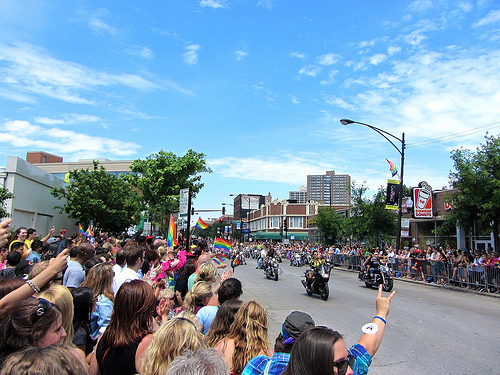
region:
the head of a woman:
[13, 287, 95, 362]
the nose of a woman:
[46, 313, 96, 350]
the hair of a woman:
[102, 280, 169, 340]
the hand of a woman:
[356, 282, 422, 320]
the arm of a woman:
[338, 278, 413, 362]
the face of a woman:
[29, 308, 81, 363]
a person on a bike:
[279, 248, 354, 308]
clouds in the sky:
[179, 9, 454, 107]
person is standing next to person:
[87, 279, 157, 372]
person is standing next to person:
[79, 261, 116, 361]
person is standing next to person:
[283, 327, 353, 372]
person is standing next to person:
[243, 284, 397, 372]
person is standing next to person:
[212, 300, 273, 371]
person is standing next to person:
[205, 300, 240, 344]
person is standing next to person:
[162, 347, 229, 372]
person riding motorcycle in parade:
[301, 249, 337, 300]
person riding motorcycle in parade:
[356, 257, 396, 294]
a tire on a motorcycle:
[318, 277, 332, 305]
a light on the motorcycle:
[317, 265, 330, 281]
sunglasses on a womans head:
[30, 295, 53, 322]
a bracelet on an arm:
[24, 276, 49, 300]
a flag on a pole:
[384, 156, 407, 185]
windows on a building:
[287, 208, 305, 229]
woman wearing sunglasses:
[329, 350, 364, 370]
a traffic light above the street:
[216, 203, 229, 218]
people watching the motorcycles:
[152, 265, 235, 334]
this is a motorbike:
[303, 247, 335, 299]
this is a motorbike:
[361, 245, 398, 290]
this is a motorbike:
[265, 245, 281, 284]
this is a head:
[291, 314, 357, 374]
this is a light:
[338, 116, 363, 130]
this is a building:
[247, 201, 311, 239]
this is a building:
[307, 175, 350, 207]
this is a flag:
[212, 231, 227, 247]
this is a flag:
[195, 215, 210, 230]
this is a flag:
[166, 212, 183, 245]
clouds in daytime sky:
[3, 1, 498, 206]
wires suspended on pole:
[400, 116, 497, 155]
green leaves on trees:
[56, 158, 148, 229]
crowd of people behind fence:
[320, 243, 497, 290]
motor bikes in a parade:
[243, 238, 393, 300]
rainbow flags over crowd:
[76, 215, 232, 257]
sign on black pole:
[178, 185, 194, 246]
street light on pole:
[339, 115, 404, 247]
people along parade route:
[0, 229, 350, 374]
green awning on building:
[253, 230, 320, 241]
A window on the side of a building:
[292, 217, 297, 229]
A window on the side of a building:
[297, 217, 302, 228]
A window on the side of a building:
[286, 218, 294, 228]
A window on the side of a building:
[272, 215, 279, 230]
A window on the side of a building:
[268, 216, 274, 227]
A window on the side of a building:
[251, 222, 254, 232]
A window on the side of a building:
[325, 185, 329, 190]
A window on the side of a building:
[325, 195, 331, 200]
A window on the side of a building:
[311, 189, 316, 194]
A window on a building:
[299, 218, 303, 228]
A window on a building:
[295, 217, 299, 228]